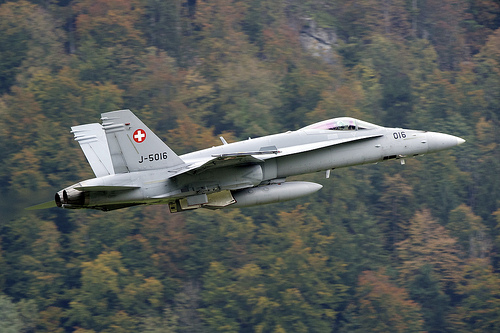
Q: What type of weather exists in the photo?
A: Sunny.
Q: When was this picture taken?
A: Daylight.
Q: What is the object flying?
A: An airplane.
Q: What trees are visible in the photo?
A: Trees.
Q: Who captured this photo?
A: A photographer.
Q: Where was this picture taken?
A: In the sky.